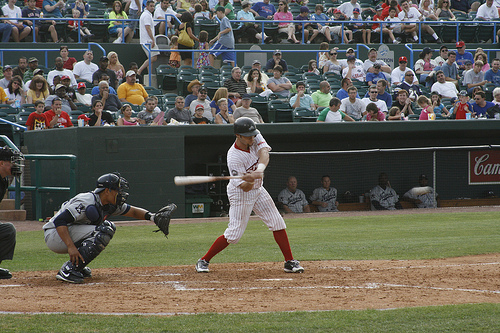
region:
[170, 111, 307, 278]
batter ready to swing bat at ball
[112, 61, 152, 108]
man in bright orange shirt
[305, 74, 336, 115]
man in lime green shirt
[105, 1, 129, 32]
person in florescent yellow shirt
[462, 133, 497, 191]
edge of coco cola advertisement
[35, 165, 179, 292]
man crouched to catch ball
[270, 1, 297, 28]
woman in dark pink blouse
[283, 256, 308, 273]
a man's tennis shoe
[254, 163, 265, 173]
a white wristband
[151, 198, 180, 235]
a black baseball glove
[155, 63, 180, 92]
a green stadium seat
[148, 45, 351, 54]
a long blue pole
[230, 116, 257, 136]
a black baseball helmet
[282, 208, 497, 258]
a section of green grass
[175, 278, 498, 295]
a long white line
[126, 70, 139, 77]
a tan baseball cap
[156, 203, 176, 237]
a black baseball glove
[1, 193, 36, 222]
part of a stairway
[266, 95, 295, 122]
a green stadium seat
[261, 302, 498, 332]
a section of green grass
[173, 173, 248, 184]
a brown and white baseball bat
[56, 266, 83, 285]
a man's tennis shoe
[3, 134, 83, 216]
a green stair rail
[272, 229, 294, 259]
a long red sock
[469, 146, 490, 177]
a white capital letter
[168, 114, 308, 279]
man swinging baseball bat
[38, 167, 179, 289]
catcher crouched to catch ball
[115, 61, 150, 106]
large man in orange shirt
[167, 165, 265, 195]
horizontal white baseball bat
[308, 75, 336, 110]
person in lime green shirt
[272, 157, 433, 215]
players watching in the dugout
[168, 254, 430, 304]
batters box drawn on field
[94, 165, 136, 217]
catcher wearing face mask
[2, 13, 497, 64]
blue handrail in bleachers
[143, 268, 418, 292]
the lines in the dirt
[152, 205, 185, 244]
the mit is black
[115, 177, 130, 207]
the face mask is black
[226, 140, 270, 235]
the uniform is striped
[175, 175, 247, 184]
the bat is wooden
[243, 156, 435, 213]
the players in the dugout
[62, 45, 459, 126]
the crowd in the stands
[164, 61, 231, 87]
the seats are green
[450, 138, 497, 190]
sign on the dugout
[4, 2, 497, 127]
spectators sitting in stands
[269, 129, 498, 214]
players sitting in dugout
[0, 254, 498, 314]
white lines on dirt